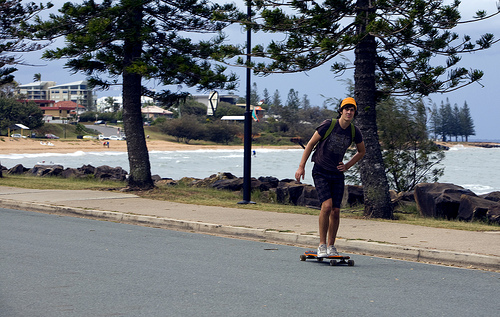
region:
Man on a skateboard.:
[298, 43, 424, 313]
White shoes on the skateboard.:
[293, 242, 374, 288]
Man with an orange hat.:
[278, 82, 401, 202]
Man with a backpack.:
[276, 89, 415, 208]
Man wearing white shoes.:
[290, 208, 380, 285]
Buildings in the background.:
[21, 60, 191, 141]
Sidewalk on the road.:
[121, 164, 246, 279]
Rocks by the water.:
[166, 98, 307, 209]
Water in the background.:
[160, 122, 336, 221]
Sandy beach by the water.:
[55, 122, 159, 185]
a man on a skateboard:
[268, 94, 368, 304]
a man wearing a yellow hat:
[343, 86, 365, 125]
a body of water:
[132, 132, 484, 182]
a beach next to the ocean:
[6, 139, 289, 166]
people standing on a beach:
[95, 132, 121, 151]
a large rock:
[413, 182, 491, 205]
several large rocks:
[22, 149, 312, 201]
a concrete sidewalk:
[44, 175, 306, 230]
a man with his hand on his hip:
[304, 89, 379, 220]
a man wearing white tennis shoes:
[275, 88, 375, 298]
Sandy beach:
[2, 136, 201, 163]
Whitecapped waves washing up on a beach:
[6, 143, 302, 161]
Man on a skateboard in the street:
[292, 91, 367, 271]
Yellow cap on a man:
[332, 95, 358, 126]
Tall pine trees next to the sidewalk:
[52, 0, 442, 225]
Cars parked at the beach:
[4, 127, 135, 157]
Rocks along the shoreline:
[11, 159, 499, 216]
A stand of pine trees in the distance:
[427, 93, 498, 151]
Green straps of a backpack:
[311, 116, 363, 144]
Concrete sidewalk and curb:
[6, 181, 498, 265]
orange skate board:
[301, 238, 351, 266]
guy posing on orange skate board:
[291, 91, 376, 271]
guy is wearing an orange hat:
[317, 89, 369, 127]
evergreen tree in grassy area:
[49, 0, 218, 212]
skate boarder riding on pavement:
[0, 203, 492, 314]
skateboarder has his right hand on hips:
[290, 82, 380, 269]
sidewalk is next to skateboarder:
[1, 184, 498, 274]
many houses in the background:
[18, 12, 287, 141]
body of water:
[3, 144, 498, 182]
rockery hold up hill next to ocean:
[1, 149, 499, 218]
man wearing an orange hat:
[299, 97, 372, 274]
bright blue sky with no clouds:
[6, 2, 491, 141]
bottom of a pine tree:
[54, 1, 227, 193]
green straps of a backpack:
[319, 113, 370, 147]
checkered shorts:
[307, 166, 351, 216]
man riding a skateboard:
[296, 85, 365, 276]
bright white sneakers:
[314, 236, 347, 259]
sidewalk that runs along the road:
[10, 177, 498, 287]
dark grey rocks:
[205, 157, 497, 219]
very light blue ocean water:
[71, 139, 498, 194]